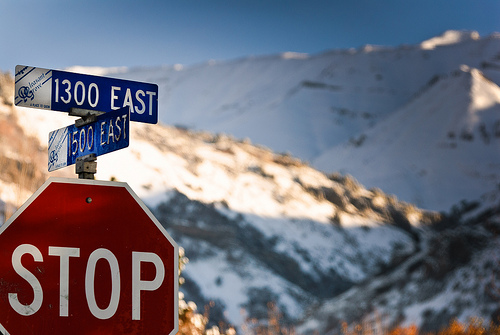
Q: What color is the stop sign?
A: Red and white.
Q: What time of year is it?
A: Winter.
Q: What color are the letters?
A: White.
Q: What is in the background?
A: Mountains.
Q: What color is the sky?
A: Blue.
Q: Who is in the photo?
A: Nobody.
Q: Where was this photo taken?
A: At the intersection of 1500 East and 1300 East.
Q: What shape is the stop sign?
A: Octagon.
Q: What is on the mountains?
A: Snow.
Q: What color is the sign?
A: Red and White.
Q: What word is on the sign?
A: Stop.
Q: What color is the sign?
A: Blue and White.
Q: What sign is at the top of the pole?
A: 1300 East.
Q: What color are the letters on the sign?
A: White.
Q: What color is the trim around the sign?
A: White.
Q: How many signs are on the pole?
A: 3.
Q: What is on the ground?
A: Snow.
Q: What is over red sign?
A: Two blue signs.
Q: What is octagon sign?
A: Red stop sign.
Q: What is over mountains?
A: Blue sky.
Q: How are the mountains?
A: Partially snow covered.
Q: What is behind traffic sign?
A: Brown leaves.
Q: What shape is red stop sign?
A: Octagon.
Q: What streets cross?
A: 1300 and 1500 East.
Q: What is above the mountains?
A: Blue sky.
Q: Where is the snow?
A: On the mountains.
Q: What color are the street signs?
A: Blue and white.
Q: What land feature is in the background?
A: Mountains.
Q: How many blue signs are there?
A: Two.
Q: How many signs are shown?
A: Three.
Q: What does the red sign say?
A: Stop.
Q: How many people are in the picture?
A: Zero.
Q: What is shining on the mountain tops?
A: Sunshine.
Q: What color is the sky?
A: Blue.